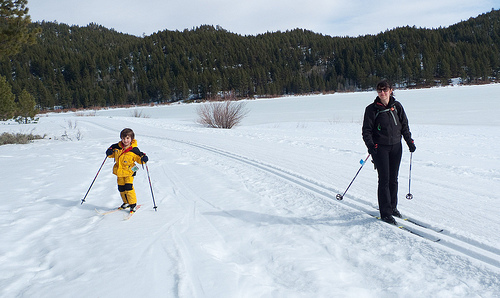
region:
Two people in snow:
[78, 68, 442, 276]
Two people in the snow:
[79, 70, 438, 235]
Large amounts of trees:
[26, 21, 474, 75]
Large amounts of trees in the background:
[25, 17, 480, 65]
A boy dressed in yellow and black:
[82, 125, 173, 215]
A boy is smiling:
[86, 120, 163, 224]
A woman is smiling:
[353, 75, 439, 230]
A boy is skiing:
[61, 125, 177, 233]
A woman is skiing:
[332, 76, 457, 248]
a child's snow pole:
[78, 153, 108, 203]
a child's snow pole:
[140, 157, 158, 209]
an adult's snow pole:
[336, 153, 370, 202]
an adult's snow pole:
[406, 151, 412, 201]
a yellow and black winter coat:
[103, 140, 143, 176]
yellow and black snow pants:
[116, 175, 138, 208]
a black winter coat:
[362, 96, 412, 150]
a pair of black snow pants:
[374, 146, 403, 213]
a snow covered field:
[0, 84, 499, 296]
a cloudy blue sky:
[18, 0, 498, 38]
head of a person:
[367, 79, 412, 110]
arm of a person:
[362, 115, 392, 160]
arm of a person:
[390, 105, 424, 143]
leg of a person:
[365, 152, 423, 213]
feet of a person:
[363, 202, 423, 242]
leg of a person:
[110, 175, 155, 207]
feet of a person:
[117, 199, 148, 216]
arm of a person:
[105, 149, 115, 163]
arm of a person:
[129, 148, 150, 165]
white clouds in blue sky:
[126, 10, 143, 17]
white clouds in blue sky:
[338, 6, 376, 34]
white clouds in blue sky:
[422, 6, 459, 24]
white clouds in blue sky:
[317, 6, 355, 33]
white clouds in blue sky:
[268, 6, 305, 31]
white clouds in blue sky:
[240, 3, 282, 28]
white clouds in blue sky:
[138, 13, 172, 33]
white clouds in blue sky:
[210, 5, 241, 26]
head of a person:
[369, 69, 406, 103]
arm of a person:
[357, 103, 395, 138]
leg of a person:
[372, 153, 394, 210]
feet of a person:
[367, 211, 405, 242]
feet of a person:
[116, 196, 150, 220]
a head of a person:
[115, 118, 145, 150]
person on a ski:
[55, 95, 207, 240]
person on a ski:
[323, 28, 438, 230]